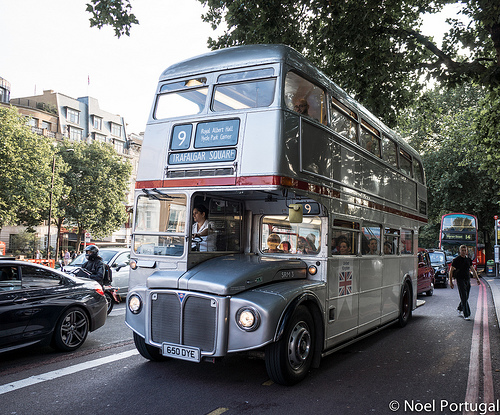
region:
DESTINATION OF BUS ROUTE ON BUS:
[164, 118, 249, 176]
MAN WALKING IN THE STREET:
[446, 243, 481, 325]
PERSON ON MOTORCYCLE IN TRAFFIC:
[58, 239, 120, 316]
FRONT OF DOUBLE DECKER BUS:
[123, 45, 328, 385]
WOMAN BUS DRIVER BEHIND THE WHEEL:
[180, 201, 222, 261]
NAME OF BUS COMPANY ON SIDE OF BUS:
[334, 255, 359, 320]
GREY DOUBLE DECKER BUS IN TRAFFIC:
[116, 46, 446, 372]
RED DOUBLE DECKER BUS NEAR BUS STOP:
[436, 207, 481, 283]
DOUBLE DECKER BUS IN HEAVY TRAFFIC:
[9, 32, 491, 413]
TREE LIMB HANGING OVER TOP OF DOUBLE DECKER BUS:
[226, 3, 496, 92]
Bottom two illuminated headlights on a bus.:
[128, 295, 258, 328]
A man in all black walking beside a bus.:
[447, 243, 482, 321]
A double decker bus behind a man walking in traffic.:
[436, 211, 480, 276]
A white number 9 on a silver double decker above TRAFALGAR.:
[175, 130, 186, 146]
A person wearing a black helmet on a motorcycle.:
[76, 245, 107, 287]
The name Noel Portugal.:
[403, 398, 499, 413]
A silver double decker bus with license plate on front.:
[123, 40, 430, 387]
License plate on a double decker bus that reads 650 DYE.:
[160, 341, 200, 363]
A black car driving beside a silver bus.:
[3, 257, 110, 360]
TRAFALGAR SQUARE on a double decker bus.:
[170, 146, 241, 165]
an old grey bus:
[117, 42, 454, 377]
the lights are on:
[237, 279, 258, 345]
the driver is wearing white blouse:
[156, 208, 221, 243]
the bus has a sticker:
[328, 259, 375, 301]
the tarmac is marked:
[78, 326, 208, 413]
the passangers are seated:
[268, 216, 414, 252]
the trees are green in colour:
[20, 113, 103, 194]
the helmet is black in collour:
[65, 238, 105, 263]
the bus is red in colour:
[433, 202, 495, 256]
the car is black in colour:
[1, 262, 111, 344]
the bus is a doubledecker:
[135, 39, 432, 367]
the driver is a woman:
[138, 200, 217, 250]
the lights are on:
[116, 279, 277, 350]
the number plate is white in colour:
[153, 338, 201, 370]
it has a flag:
[332, 274, 357, 296]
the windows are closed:
[320, 210, 415, 260]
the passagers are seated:
[266, 213, 321, 260]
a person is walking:
[453, 232, 480, 331]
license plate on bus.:
[155, 347, 199, 359]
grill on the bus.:
[190, 306, 208, 329]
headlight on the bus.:
[238, 305, 254, 333]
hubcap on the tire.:
[287, 330, 309, 367]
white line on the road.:
[15, 368, 62, 393]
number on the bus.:
[169, 126, 190, 151]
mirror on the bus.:
[279, 198, 305, 227]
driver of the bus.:
[192, 206, 207, 243]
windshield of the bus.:
[144, 205, 173, 221]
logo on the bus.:
[331, 272, 354, 297]